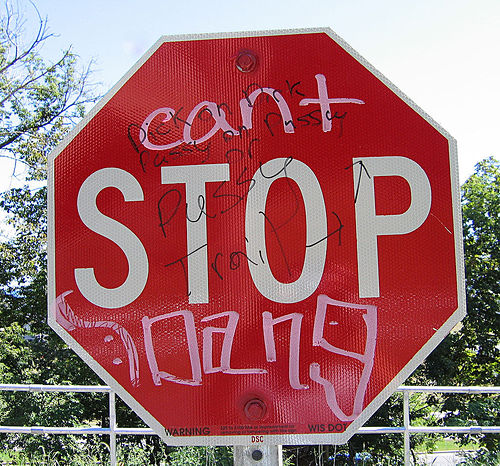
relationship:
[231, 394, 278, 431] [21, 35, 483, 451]
bolt on sign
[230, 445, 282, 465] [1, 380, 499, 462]
pole part of fence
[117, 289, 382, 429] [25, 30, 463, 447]
graffiti on stop sign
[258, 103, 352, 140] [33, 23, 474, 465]
graffiti on stop sign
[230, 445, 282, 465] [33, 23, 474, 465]
pole attached to stop sign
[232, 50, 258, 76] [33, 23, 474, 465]
metal bolt on top of stop sign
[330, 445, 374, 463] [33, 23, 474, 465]
flowers underneath stop sign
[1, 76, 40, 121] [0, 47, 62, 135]
branch of tree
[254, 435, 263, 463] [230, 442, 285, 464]
bolt of pole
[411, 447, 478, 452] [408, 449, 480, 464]
curbing beside road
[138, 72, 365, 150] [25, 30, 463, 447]
graffiti spray painted on stop sign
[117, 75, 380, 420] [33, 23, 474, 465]
graffiti in stop sign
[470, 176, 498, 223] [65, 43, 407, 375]
trees in sign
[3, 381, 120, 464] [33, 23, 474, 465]
metal fence behind stop sign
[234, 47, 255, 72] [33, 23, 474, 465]
bolt on stop sign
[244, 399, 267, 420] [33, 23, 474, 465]
bolt on stop sign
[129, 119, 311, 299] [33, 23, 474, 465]
graffiti on stop sign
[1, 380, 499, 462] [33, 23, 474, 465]
fence behind stop sign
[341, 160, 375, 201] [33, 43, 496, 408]
graffiti on stop sign